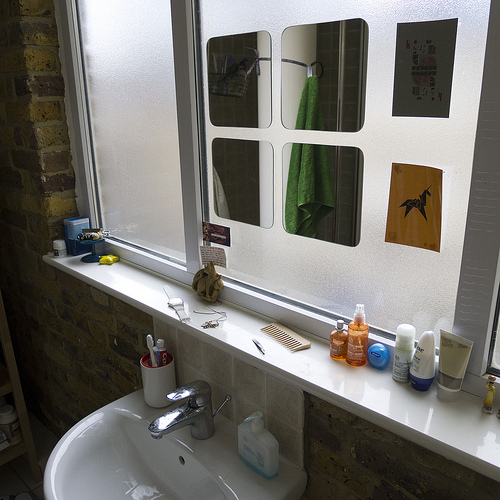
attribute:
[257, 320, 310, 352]
comb —  light brown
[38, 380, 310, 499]
sink — white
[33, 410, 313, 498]
sink —  white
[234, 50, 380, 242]
squares — mirrored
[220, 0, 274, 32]
glass — frosted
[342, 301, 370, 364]
spray bottle — orange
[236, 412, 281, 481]
bottle — almost empty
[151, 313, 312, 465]
backsplash — white, beige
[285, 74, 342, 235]
towel —  green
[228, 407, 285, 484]
container — blue, white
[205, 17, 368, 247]
mirror —  four piece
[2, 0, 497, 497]
bathroom — wide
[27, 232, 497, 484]
shelf — long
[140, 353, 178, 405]
cup — white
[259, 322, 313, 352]
comb — brown, large